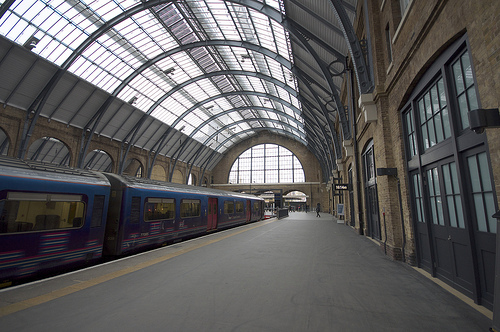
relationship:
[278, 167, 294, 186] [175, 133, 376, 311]
window at end of terminal